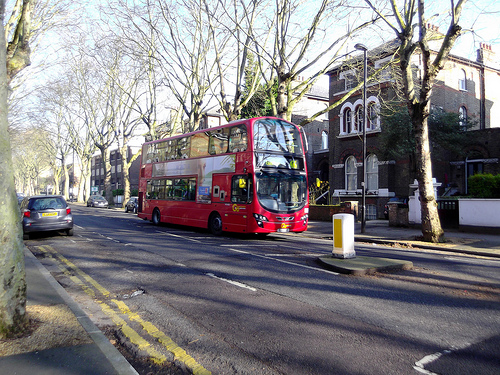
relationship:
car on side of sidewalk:
[21, 193, 75, 243] [353, 219, 499, 258]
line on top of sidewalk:
[43, 244, 213, 374] [353, 219, 499, 258]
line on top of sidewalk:
[205, 270, 259, 293] [353, 219, 499, 258]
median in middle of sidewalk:
[315, 211, 414, 277] [353, 219, 499, 258]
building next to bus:
[323, 19, 499, 220] [136, 114, 311, 235]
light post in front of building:
[353, 41, 367, 236] [323, 19, 499, 220]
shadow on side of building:
[412, 63, 495, 130] [323, 19, 499, 220]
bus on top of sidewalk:
[136, 114, 311, 235] [353, 219, 499, 258]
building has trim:
[323, 19, 499, 220] [331, 158, 396, 170]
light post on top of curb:
[353, 41, 367, 236] [355, 235, 500, 259]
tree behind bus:
[196, 0, 398, 128] [136, 114, 311, 235]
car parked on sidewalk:
[21, 193, 75, 243] [353, 219, 499, 258]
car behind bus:
[121, 196, 139, 215] [136, 114, 311, 235]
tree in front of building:
[362, 0, 468, 244] [323, 19, 499, 220]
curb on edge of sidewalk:
[355, 235, 500, 259] [307, 219, 499, 258]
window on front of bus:
[251, 118, 304, 156] [136, 114, 311, 235]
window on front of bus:
[254, 166, 308, 212] [136, 114, 311, 235]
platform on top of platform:
[316, 251, 413, 276] [316, 251, 415, 276]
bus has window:
[136, 114, 311, 235] [143, 176, 197, 201]